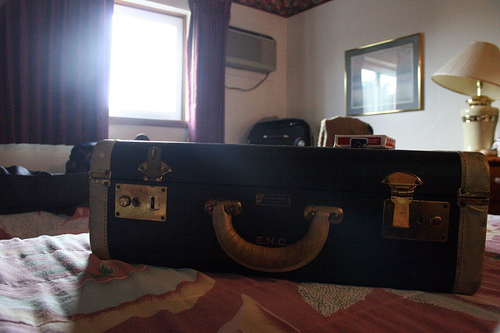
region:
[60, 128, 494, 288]
small black brief case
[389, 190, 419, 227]
metal latch on case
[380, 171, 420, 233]
silver latch on case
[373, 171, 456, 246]
silver lock on case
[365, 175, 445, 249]
metal lock on case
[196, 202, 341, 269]
handle of the case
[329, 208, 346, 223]
screw on side of handle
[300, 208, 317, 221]
screw on side of handle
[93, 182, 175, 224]
metal lock on case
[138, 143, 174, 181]
missing latch on case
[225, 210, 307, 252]
handle of the case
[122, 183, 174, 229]
latch of the case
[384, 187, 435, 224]
latch of the case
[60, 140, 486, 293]
case on the bed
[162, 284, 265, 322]
sheet on the bed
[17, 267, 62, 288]
sun on the bed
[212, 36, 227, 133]
curtain on the right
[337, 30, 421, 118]
picture on the wall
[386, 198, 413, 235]
latch closed on right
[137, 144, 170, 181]
latch open on left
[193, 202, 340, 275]
bronze handle in middle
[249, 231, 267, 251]
letter e on case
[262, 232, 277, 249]
letter n on case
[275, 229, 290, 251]
letter c on case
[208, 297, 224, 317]
pink color on spread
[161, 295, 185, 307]
yellow color on spread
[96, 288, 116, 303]
light blue color on spread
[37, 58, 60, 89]
brown curtain in window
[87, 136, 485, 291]
Suitcase on the bed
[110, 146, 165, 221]
One clasp of suitcase open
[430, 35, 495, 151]
Lamp on the table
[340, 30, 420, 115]
Picture on the wall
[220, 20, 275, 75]
AIr conditioning unit in the wall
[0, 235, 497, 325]
Quilt on the bed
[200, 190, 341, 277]
Handle of the suitcase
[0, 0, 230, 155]
Drapes on the window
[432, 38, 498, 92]
White lampshade slighlty askew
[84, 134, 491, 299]
old leather suitcase on bed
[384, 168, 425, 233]
latch on old suitcase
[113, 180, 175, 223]
lock on old suitcase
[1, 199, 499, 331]
multi-colored bedspread covering bed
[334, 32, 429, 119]
decor affixed to wall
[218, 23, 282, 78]
air conditioner mounted in wall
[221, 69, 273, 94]
power cord to air conditioner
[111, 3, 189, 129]
window with sunlight shining through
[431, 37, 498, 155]
lamp with tilted shade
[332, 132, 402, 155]
deck of playing cards